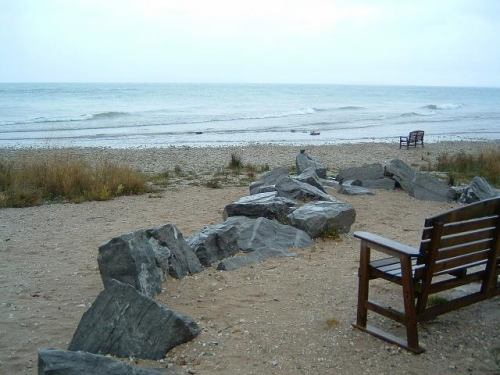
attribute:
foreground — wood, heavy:
[4, 146, 493, 372]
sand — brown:
[203, 275, 318, 355]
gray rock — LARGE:
[105, 232, 196, 277]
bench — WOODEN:
[341, 192, 487, 352]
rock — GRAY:
[70, 279, 202, 359]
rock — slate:
[92, 219, 199, 293]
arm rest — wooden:
[352, 227, 412, 264]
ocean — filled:
[0, 73, 495, 155]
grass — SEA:
[451, 147, 495, 176]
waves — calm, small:
[90, 104, 147, 139]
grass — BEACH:
[3, 144, 134, 223]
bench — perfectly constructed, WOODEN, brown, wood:
[353, 196, 498, 357]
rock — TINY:
[265, 353, 276, 363]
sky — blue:
[7, 0, 491, 82]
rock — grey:
[224, 190, 294, 221]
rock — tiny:
[65, 270, 207, 361]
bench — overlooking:
[389, 117, 440, 152]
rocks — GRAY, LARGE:
[30, 155, 483, 373]